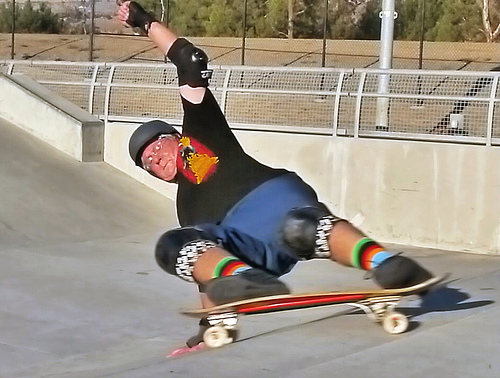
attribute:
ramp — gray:
[0, 116, 183, 251]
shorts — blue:
[176, 173, 332, 282]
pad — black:
[167, 38, 213, 89]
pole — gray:
[376, 0, 397, 132]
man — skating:
[117, 0, 433, 359]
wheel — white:
[383, 312, 410, 335]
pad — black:
[278, 203, 349, 260]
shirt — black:
[176, 85, 296, 229]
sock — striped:
[350, 236, 393, 272]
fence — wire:
[0, 0, 499, 107]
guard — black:
[125, 0, 159, 38]